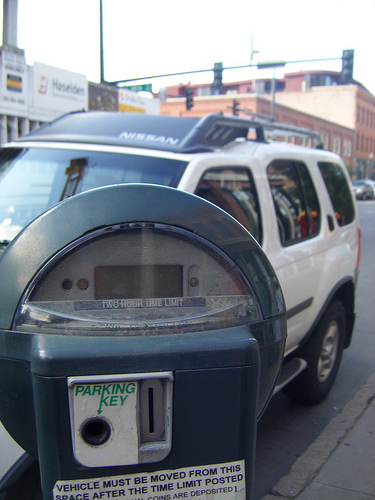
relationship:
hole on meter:
[73, 408, 115, 449] [29, 197, 282, 486]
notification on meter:
[73, 266, 222, 315] [29, 197, 282, 486]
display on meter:
[95, 254, 121, 287] [29, 197, 282, 486]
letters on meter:
[78, 379, 136, 414] [29, 197, 282, 486]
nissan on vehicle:
[119, 124, 180, 154] [246, 108, 351, 309]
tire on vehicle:
[286, 296, 344, 408] [246, 108, 351, 309]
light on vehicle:
[340, 216, 369, 273] [246, 108, 351, 309]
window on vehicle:
[265, 149, 325, 263] [246, 108, 351, 309]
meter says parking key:
[29, 197, 282, 486] [63, 383, 118, 412]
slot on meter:
[140, 384, 169, 435] [29, 197, 282, 486]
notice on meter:
[192, 456, 224, 493] [29, 197, 282, 486]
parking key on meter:
[63, 383, 118, 412] [29, 197, 282, 486]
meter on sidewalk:
[29, 197, 282, 486] [323, 450, 365, 467]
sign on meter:
[114, 303, 180, 356] [29, 197, 282, 486]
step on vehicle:
[274, 344, 309, 390] [246, 108, 351, 309]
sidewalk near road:
[323, 450, 365, 467] [264, 430, 296, 444]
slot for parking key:
[140, 384, 169, 435] [63, 383, 118, 412]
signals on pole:
[334, 46, 360, 81] [196, 45, 296, 74]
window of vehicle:
[265, 149, 325, 263] [246, 108, 351, 309]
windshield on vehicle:
[97, 153, 161, 177] [246, 108, 351, 309]